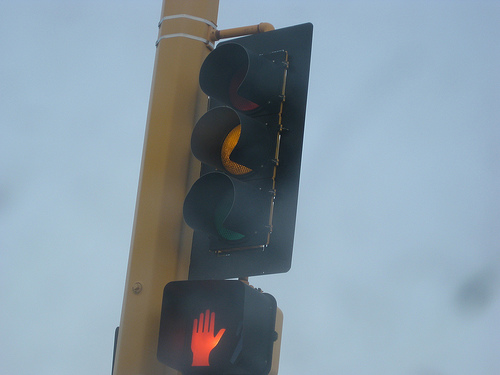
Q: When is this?
A: Daytime.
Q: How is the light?
A: Lit up.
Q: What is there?
A: Traffic light.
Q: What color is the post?
A: Yellow.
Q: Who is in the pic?
A: No one.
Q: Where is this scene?
A: Street.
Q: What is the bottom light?
A: A hand.